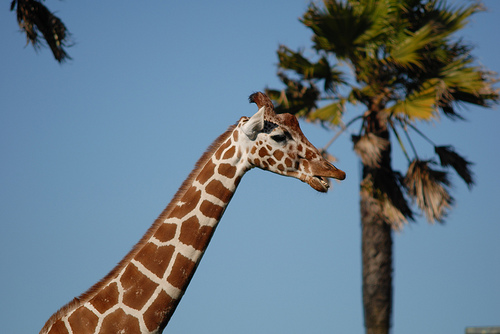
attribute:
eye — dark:
[261, 122, 307, 166]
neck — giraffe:
[44, 159, 252, 331]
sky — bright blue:
[12, 39, 232, 199]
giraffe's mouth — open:
[30, 96, 354, 332]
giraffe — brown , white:
[30, 90, 353, 330]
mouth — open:
[307, 155, 364, 215]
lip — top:
[313, 163, 349, 180]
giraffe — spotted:
[80, 96, 347, 324]